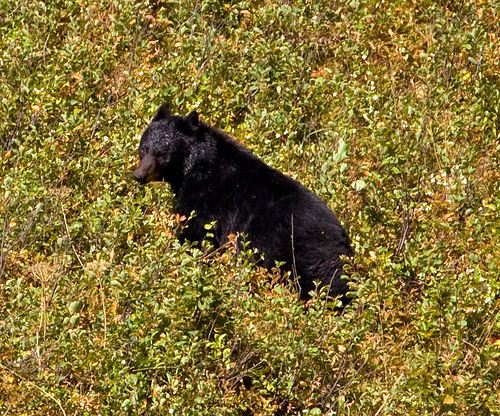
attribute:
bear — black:
[127, 104, 356, 309]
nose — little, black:
[127, 169, 144, 184]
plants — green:
[53, 230, 284, 372]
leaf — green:
[201, 222, 213, 231]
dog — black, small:
[134, 100, 355, 312]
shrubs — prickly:
[0, 0, 500, 408]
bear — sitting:
[121, 95, 372, 303]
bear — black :
[90, 91, 387, 311]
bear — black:
[120, 99, 383, 326]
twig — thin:
[285, 212, 315, 290]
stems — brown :
[202, 25, 489, 185]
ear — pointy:
[154, 100, 173, 119]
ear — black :
[152, 93, 176, 115]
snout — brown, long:
[132, 153, 157, 180]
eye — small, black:
[137, 145, 147, 156]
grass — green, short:
[104, 255, 314, 368]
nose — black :
[110, 140, 164, 189]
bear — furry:
[69, 63, 364, 310]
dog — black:
[103, 91, 411, 338]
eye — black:
[132, 140, 175, 164]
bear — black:
[133, 90, 351, 311]